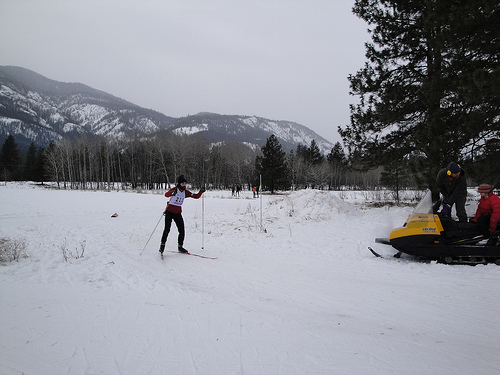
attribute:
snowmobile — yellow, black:
[366, 192, 499, 264]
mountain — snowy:
[0, 67, 338, 158]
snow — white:
[0, 180, 499, 374]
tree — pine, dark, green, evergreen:
[335, 4, 499, 208]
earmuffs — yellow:
[445, 159, 462, 176]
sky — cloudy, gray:
[1, 1, 499, 154]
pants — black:
[160, 213, 186, 249]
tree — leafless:
[43, 144, 64, 187]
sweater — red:
[166, 188, 200, 214]